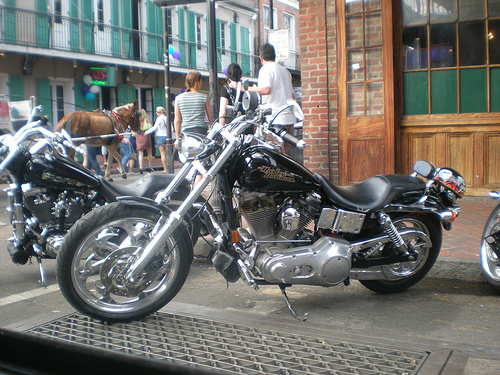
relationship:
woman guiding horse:
[146, 107, 171, 170] [59, 102, 141, 177]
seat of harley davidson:
[315, 173, 427, 207] [55, 80, 467, 320]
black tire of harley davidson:
[352, 210, 443, 294] [55, 80, 467, 320]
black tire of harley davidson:
[55, 201, 194, 321] [55, 80, 467, 320]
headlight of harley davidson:
[176, 130, 220, 162] [55, 80, 467, 320]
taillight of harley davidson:
[437, 206, 457, 221] [55, 80, 467, 320]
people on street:
[174, 44, 299, 219] [1, 166, 498, 374]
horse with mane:
[50, 69, 166, 177] [106, 102, 141, 114]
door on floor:
[144, 2, 178, 64] [51, 42, 168, 68]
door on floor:
[223, 16, 245, 66] [51, 42, 168, 68]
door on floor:
[68, 2, 93, 44] [51, 42, 168, 68]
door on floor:
[24, 0, 54, 44] [51, 42, 168, 68]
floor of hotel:
[51, 42, 168, 68] [37, 1, 219, 124]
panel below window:
[406, 127, 438, 173] [405, 0, 499, 114]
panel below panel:
[441, 127, 474, 188] [482, 127, 499, 190]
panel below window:
[482, 127, 499, 190] [405, 0, 499, 114]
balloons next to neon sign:
[76, 74, 101, 104] [87, 65, 113, 84]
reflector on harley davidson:
[224, 222, 250, 246] [55, 80, 467, 320]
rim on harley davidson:
[78, 225, 169, 304] [55, 80, 467, 320]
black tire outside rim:
[55, 201, 194, 321] [71, 217, 179, 314]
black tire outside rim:
[352, 210, 443, 294] [380, 216, 431, 281]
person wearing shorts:
[129, 96, 183, 186] [146, 127, 179, 152]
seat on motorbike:
[315, 173, 427, 207] [56, 74, 455, 322]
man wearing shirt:
[226, 39, 303, 148] [254, 61, 299, 126]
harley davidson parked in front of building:
[55, 80, 467, 320] [285, 5, 448, 215]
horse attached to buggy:
[50, 69, 166, 177] [0, 94, 67, 152]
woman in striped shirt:
[169, 67, 217, 167] [169, 90, 211, 135]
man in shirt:
[226, 42, 296, 155] [259, 59, 293, 107]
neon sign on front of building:
[87, 65, 113, 84] [4, 3, 242, 130]